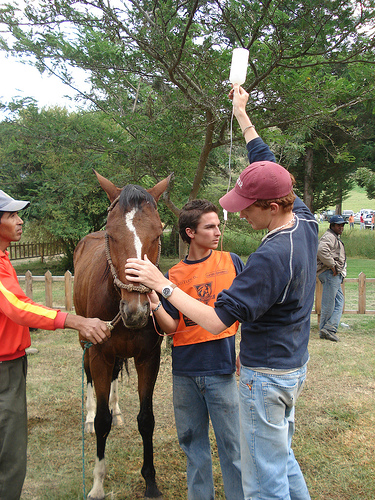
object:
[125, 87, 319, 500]
man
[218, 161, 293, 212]
cap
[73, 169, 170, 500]
horse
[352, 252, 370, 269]
grass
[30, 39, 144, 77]
leaves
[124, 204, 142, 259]
white stripe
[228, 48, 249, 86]
white bottle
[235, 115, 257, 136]
wrist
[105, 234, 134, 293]
rope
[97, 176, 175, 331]
horse's head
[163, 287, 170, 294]
black faced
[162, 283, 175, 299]
watch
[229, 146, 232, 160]
white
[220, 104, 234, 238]
line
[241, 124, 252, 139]
metallic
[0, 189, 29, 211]
grey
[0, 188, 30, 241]
on the head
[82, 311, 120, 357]
string hanging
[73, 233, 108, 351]
horse's side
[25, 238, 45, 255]
part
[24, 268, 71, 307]
fence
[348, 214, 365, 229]
people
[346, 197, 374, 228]
background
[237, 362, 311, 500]
jeans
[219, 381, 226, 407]
blue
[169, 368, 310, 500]
pants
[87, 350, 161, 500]
leg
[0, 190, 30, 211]
grey hat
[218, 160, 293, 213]
hat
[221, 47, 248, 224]
tube attached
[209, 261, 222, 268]
bright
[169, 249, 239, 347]
orange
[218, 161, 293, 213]
maroon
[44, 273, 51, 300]
brown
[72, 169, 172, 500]
brown horse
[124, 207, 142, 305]
white markings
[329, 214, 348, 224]
blue cap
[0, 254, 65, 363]
red windbreaker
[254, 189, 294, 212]
red hair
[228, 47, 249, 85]
iv bottle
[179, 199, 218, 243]
brown hair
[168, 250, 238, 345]
vest